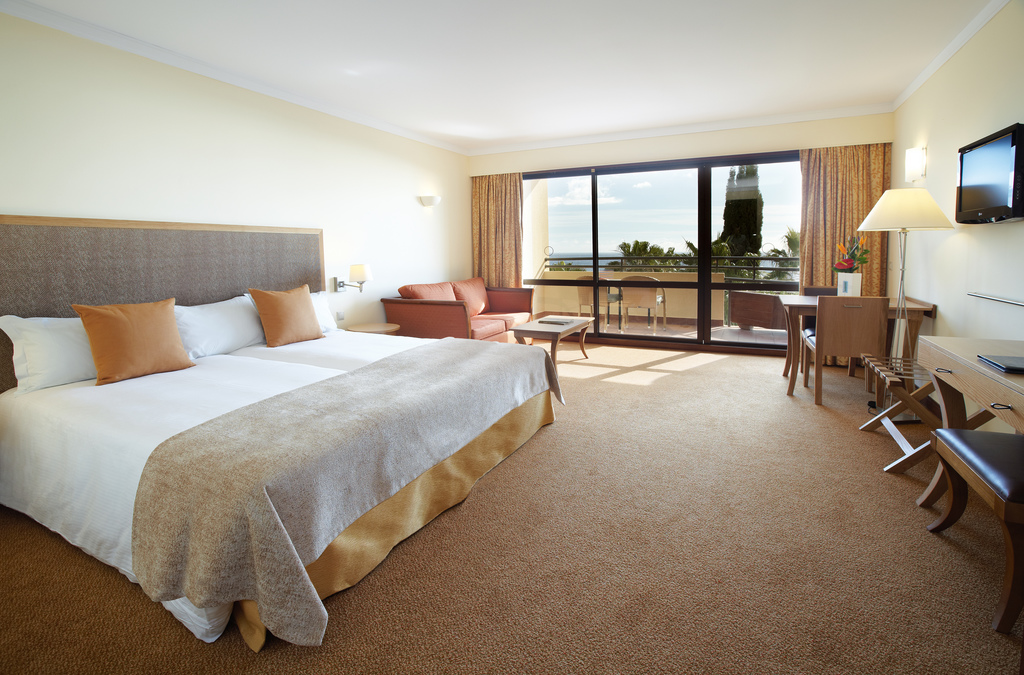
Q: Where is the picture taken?
A: In a large hotel room in a city.